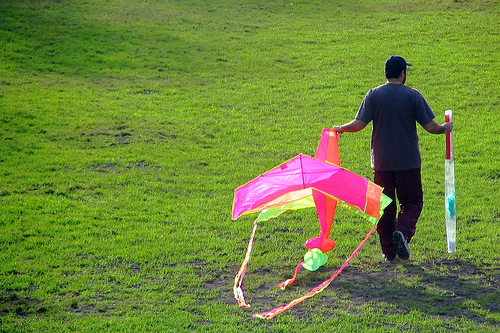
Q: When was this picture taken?
A: Daytime.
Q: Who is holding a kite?
A: The man.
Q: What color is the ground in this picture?
A: Green.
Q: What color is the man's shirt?
A: Blue.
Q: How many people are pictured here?
A: One.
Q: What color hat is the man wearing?
A: Blue.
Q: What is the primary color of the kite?
A: Pink.